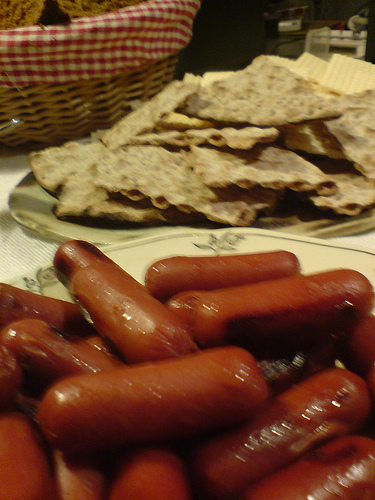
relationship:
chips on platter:
[65, 59, 372, 213] [12, 160, 374, 244]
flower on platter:
[179, 224, 262, 266] [0, 224, 364, 326]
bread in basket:
[2, 3, 125, 29] [0, 55, 178, 146]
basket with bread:
[0, 55, 178, 146] [2, 0, 139, 32]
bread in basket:
[2, 3, 110, 19] [10, 22, 184, 136]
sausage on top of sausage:
[34, 343, 274, 454] [108, 444, 186, 499]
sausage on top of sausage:
[140, 247, 309, 300] [34, 343, 274, 454]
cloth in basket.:
[0, 0, 200, 88] [3, 8, 183, 134]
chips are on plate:
[36, 51, 375, 239] [11, 135, 373, 250]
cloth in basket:
[0, 0, 200, 88] [0, 55, 178, 146]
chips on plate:
[36, 51, 375, 239] [0, 133, 373, 233]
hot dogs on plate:
[0, 240, 375, 500] [7, 229, 372, 499]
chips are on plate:
[36, 51, 375, 239] [11, 119, 373, 245]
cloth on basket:
[9, 8, 197, 73] [0, 2, 217, 133]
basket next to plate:
[0, 55, 178, 146] [110, 190, 345, 276]